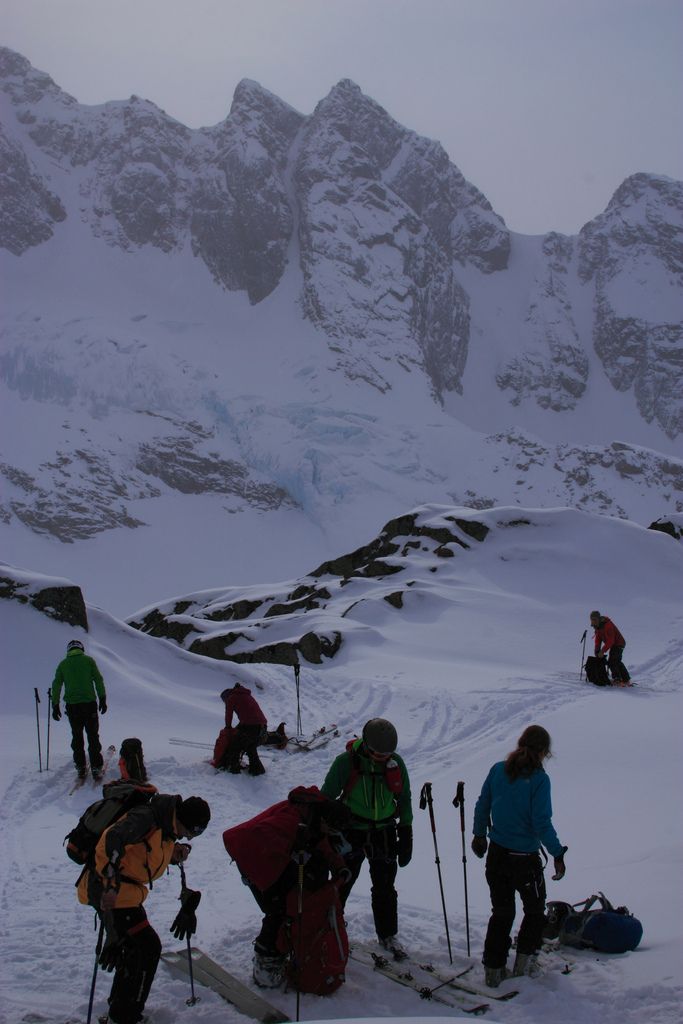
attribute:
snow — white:
[234, 212, 352, 347]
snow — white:
[137, 188, 256, 300]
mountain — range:
[80, 120, 578, 930]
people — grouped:
[88, 668, 571, 971]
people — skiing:
[2, 612, 625, 961]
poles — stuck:
[409, 760, 508, 972]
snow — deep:
[182, 739, 367, 893]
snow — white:
[424, 615, 564, 775]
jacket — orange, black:
[60, 769, 255, 971]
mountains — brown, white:
[142, 141, 503, 434]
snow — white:
[408, 568, 569, 716]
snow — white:
[70, 284, 308, 471]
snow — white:
[2, 563, 680, 1018]